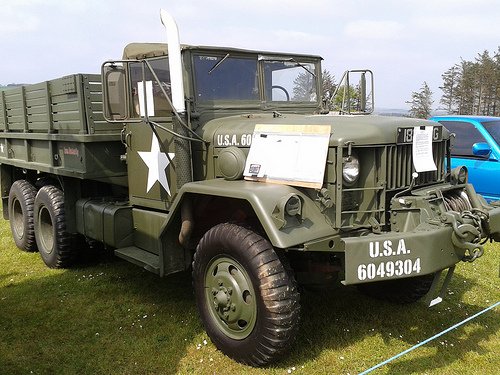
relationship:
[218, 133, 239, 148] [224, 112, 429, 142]
usa on hood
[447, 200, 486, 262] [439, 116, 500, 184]
chain on truck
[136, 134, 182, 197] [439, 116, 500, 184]
star on truck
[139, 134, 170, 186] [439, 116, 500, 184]
star on truck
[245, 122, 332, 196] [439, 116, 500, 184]
signs on truck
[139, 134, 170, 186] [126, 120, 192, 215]
star on door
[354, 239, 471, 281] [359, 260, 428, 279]
bumper has numbers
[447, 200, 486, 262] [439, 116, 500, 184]
wench on truck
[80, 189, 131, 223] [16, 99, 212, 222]
tank on side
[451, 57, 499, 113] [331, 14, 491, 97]
trees in distance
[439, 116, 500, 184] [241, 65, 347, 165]
truck for driving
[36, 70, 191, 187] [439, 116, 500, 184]
cab on truck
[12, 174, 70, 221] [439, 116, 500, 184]
tires on truck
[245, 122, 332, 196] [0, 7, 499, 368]
sign on lorry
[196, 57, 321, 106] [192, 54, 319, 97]
wipers at top of windshield